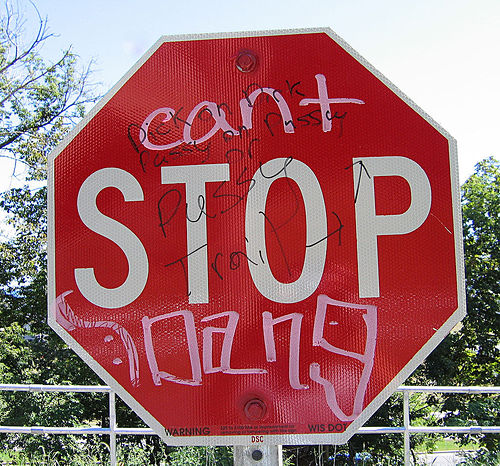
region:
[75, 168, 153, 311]
white letter on sign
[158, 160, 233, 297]
white letter on sign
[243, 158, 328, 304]
white letter on sign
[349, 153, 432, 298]
white letter on sign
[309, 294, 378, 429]
white letter on sign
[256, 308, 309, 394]
white letter on sign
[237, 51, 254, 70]
Rivot on top of sign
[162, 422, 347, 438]
Black warning sign on bottom of stop sign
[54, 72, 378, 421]
Graffiti in middle of stop sign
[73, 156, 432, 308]
White lettering in middle of sign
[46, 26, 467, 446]
Sign on pole in octagon shape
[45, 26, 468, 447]
Damaged sign attached to pole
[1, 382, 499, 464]
Fence behind the stop sign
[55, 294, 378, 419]
Paint sprayed on front of sign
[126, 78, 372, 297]
Black ink written on sign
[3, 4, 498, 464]
Red sign standing in front of trees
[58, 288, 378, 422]
Pink graffiti on bottom of sign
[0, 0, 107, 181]
Branches missing some leaves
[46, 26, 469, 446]
Defaced stop sign in front of metal fence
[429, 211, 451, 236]
Scratch on side of sign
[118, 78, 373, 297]
Bad words written in black ink on sign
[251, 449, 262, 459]
Rivot on metal pole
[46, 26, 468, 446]
Silver border around red sign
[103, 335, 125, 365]
Dots sprayed in pink paint on sign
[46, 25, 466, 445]
Grooved pattern on stop sign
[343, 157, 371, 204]
Black arrow on stop sign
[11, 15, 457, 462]
The sign has a white border around it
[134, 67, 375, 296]
graffiti is written on the sign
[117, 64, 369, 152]
Cant is written above the word stop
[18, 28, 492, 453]
the sign indicates that you must stop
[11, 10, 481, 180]
The sky is blue and clear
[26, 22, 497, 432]
There are several trees behind the sign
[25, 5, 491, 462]
The stop sign has been vandalized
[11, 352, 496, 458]
There is a metal railing behind the sign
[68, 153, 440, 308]
The letters are written in white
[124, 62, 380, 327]
questionable language has been written on the sign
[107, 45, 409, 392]
a sign on apole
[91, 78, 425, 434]
a sign on a metal pole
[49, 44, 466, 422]
a sign that is red and white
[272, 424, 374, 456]
the white edge of a stop sign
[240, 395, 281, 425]
a red bolt on a stop sign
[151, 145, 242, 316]
a large white letter T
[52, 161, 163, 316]
a large white letter S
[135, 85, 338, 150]
graffiti on red stop sign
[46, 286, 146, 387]
graffiti on red stop sign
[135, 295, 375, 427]
graffiti on red stop sign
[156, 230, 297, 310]
graffiti on red stop sign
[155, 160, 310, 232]
graffiti on red stop sign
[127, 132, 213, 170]
graffiti on red stop sign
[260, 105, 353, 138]
graffiti on red stop sign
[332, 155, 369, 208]
graffiti on red stop sign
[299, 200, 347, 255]
graffiti on red stop sign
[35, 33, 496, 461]
A red and white stop sign.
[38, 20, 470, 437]
A stop sign with graphiti on it.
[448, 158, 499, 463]
Green trees behind the sign.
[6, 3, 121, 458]
Green trees behind the stop sign.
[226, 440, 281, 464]
A metal pole attached to the sign.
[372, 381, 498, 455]
A metal fence behind the sign.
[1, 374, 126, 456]
A metal fence behind the sign.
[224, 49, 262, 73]
A metal bolt on top of the sign.